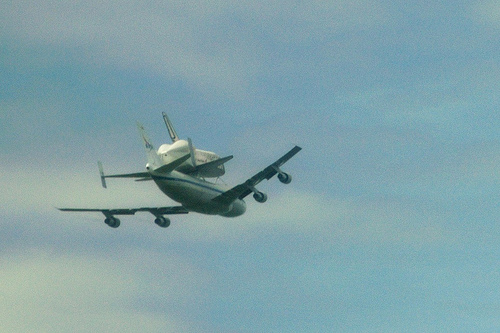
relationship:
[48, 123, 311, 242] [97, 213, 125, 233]
plane has engine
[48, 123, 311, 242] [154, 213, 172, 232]
plane has engine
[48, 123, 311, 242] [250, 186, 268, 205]
plane has engine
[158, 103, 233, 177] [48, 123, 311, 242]
space shuttle on plane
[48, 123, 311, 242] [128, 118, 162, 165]
plane has tail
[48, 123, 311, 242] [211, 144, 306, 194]
plane has wing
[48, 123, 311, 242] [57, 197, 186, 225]
plane has wing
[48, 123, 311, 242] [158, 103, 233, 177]
plane carrying space shuttle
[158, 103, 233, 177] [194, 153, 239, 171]
space shuttle has wing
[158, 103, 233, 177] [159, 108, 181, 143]
space shuttle has tail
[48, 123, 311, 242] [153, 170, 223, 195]
plane has strip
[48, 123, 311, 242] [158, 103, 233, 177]
plane has space shuttle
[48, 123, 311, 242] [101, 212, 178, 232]
plane has engines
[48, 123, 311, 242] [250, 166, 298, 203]
plane has engines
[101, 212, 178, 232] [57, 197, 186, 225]
engines on wing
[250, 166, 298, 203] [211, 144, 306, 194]
engines on wing